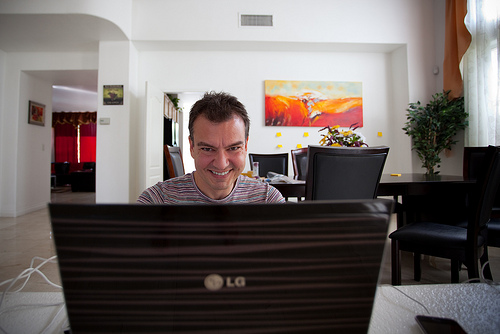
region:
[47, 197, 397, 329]
Back of the screen of an lg laptop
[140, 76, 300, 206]
Smiling man using the laptop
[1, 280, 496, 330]
Desk the laptop is sitting on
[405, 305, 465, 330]
A phone sitting on the desk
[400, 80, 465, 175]
Small plant in the corner of the room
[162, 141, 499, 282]
Dining room table and chairs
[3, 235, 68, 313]
A long white cable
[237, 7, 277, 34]
An air conditioning and heating vent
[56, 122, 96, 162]
Red curtains in the other rooms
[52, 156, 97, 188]
Several chairs in the other room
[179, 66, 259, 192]
man has brown hair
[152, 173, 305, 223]
man has striped shirt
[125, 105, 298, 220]
man sits behind laptop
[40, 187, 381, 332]
laptop is black and glossy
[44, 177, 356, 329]
laptop on grey table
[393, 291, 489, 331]
phone next to laptop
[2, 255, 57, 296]
white cables behind laptop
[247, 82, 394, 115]
orange picture on wall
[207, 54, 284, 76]
white wall around picture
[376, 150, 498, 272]
black chairs at table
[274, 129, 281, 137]
yellow sticker on wall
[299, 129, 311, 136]
yellow sticker on wall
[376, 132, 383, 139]
yellow sticker on wall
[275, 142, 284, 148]
yellow sticker on wall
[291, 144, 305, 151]
yellow sticker on wall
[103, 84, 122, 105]
picture hanging on wall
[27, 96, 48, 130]
picture hanging on wall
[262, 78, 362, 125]
picture hanging on wall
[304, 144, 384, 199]
empty black colored chair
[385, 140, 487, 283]
empty black colored chair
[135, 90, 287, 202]
Man in front of laptop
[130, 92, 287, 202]
Man in front of laptop is smiling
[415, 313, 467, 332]
Phone next to laptop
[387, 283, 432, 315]
White cable attached to phone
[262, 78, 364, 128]
Large painting on wall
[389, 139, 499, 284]
Chair in front of table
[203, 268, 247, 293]
LG logo on laptop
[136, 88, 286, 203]
Man smiling is wearing a striped shirt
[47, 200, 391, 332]
Laptop on white table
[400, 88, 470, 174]
Green plant next to window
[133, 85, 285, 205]
Man sitting behind dining table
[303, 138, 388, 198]
Chair behind man on laptop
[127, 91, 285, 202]
Man wearing striped shirt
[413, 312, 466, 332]
Phone on white table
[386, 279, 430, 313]
White cord attached to phone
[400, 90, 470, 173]
Green plant next to curtain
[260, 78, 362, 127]
Large painting hung on wall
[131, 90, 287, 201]
Man is using laptop